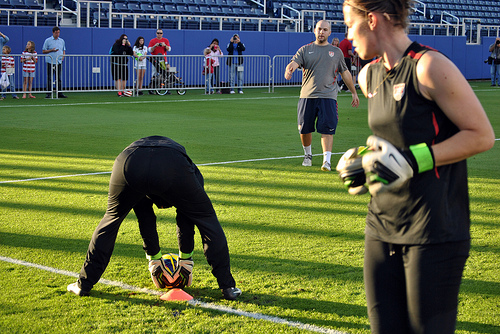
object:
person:
[132, 37, 151, 94]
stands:
[0, 1, 500, 40]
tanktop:
[357, 42, 472, 245]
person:
[42, 26, 67, 100]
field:
[0, 79, 500, 333]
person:
[335, 0, 498, 333]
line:
[0, 252, 343, 333]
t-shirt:
[290, 40, 344, 102]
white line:
[0, 150, 348, 188]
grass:
[0, 79, 500, 333]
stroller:
[143, 52, 187, 97]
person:
[19, 38, 37, 100]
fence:
[0, 50, 305, 99]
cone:
[156, 286, 198, 302]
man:
[66, 133, 244, 300]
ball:
[146, 252, 192, 295]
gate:
[54, 50, 136, 100]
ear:
[367, 11, 379, 32]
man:
[283, 17, 360, 172]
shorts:
[296, 97, 343, 136]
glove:
[357, 133, 439, 199]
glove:
[333, 146, 366, 199]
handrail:
[438, 9, 463, 38]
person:
[108, 33, 134, 98]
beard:
[317, 35, 327, 44]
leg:
[402, 241, 469, 333]